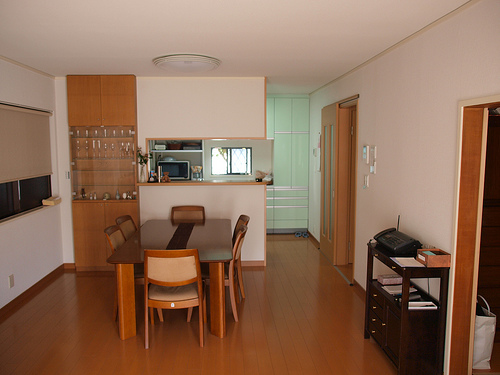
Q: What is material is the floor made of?
A: Wood.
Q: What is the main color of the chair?
A: Brown.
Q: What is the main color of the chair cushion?
A: Brown.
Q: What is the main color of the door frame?
A: Brown.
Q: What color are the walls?
A: White.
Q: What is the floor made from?
A: Hardwood planks.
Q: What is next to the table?
A: Shelves with glasses on them.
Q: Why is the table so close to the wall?
A: To save space.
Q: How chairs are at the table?
A: Six.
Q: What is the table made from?
A: Wood.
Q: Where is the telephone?
A: On top of the furniture to the right.